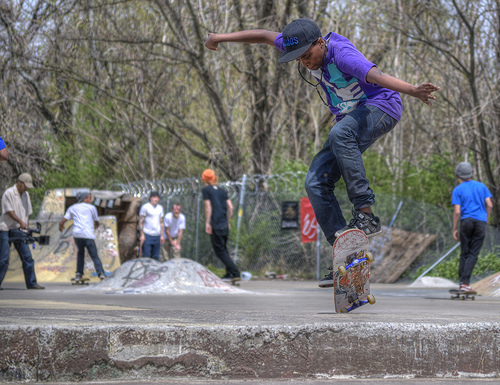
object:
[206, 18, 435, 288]
skateboarder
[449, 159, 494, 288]
skateboarder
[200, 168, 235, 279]
skateboarder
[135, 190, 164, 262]
skateboarder